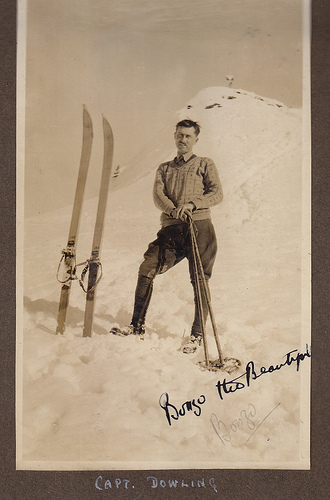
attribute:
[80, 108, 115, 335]
ski — standing, vertical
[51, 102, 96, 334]
ski — standing, vertical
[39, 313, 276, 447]
snow — white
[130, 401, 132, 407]
snow — white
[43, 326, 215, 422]
snow — white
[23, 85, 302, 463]
snow — white, fresh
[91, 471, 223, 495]
writing — white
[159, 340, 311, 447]
writing — white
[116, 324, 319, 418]
writing — grey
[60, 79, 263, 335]
photograph — sepia colored, old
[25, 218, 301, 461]
snow — white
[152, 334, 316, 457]
signatures — pre-printed, hand-signed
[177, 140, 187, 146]
mouth — open